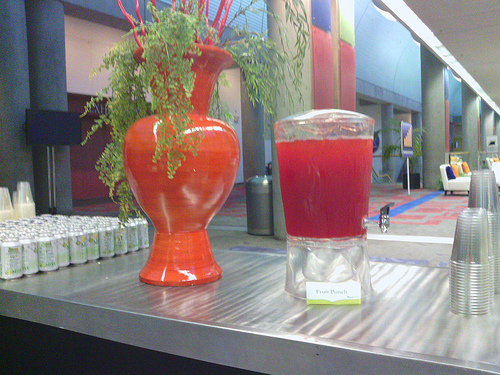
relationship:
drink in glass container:
[275, 137, 373, 238] [266, 100, 388, 312]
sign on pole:
[399, 117, 416, 157] [403, 155, 412, 193]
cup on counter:
[451, 209, 494, 268] [3, 242, 494, 372]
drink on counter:
[275, 137, 373, 238] [1, 211, 498, 371]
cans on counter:
[2, 212, 150, 289] [122, 239, 498, 371]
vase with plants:
[116, 38, 247, 285] [72, 7, 203, 221]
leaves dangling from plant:
[96, 44, 150, 199] [93, 0, 280, 194]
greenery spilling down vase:
[92, 130, 212, 213] [117, 110, 264, 267]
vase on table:
[116, 38, 247, 285] [2, 232, 498, 373]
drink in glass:
[272, 116, 372, 252] [271, 97, 381, 313]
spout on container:
[361, 200, 393, 230] [273, 107, 393, 303]